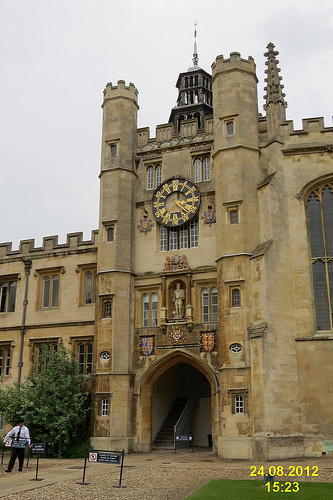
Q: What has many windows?
A: Building.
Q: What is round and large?
A: Clock.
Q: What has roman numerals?
A: The clock.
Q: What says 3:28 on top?
A: Clock.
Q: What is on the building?
A: Clock.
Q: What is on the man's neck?
A: Tie.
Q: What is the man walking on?
A: Walkway.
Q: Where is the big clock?
A: On the building front.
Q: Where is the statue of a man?
A: Under the clock.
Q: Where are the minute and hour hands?
A: On the clock.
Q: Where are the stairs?
A: Inside the building.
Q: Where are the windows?
A: On the building.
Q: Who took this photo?
A: A professional photographer.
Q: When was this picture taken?
A: In 2012.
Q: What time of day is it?
A: Noon.